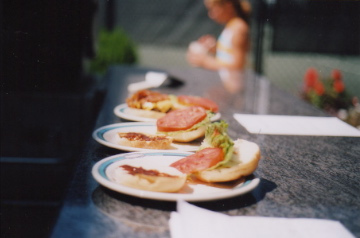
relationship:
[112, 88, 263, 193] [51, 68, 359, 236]
food on counter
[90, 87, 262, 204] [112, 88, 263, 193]
plates have sandwiches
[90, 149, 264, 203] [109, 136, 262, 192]
first plate has a burger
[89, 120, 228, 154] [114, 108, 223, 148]
middle plate has a burger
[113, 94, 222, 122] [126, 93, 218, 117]
third plate has a burger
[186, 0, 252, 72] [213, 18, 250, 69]
kid wearing a shirt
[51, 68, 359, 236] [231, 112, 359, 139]
counter has paper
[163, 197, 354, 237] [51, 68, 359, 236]
paper on counter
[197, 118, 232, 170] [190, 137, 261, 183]
lettuce on bread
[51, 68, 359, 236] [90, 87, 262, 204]
counter has three plates